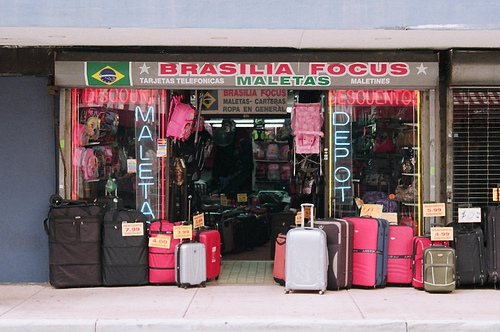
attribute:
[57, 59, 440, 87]
sign — green, yellow, white, grey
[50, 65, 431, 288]
storefront — gated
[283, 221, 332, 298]
luggage — silver, for sale, tall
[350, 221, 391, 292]
bag — luggage, pink, black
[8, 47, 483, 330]
store — brazillian, big, luggage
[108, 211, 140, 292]
luggage — black, large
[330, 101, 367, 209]
sign — neon, blue, depot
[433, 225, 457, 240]
tag — price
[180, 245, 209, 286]
bag — grey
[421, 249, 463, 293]
luggage — greenish, brown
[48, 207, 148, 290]
bags — black, luggage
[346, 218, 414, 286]
bags — pink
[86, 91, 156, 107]
sign — pink, discount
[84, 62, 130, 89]
flag — brazillian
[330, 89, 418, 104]
lettering — spanish, pink, desquentos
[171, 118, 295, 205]
inside — dark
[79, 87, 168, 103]
discount — written, red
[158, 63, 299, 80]
brasilia — red, written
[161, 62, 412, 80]
writing — red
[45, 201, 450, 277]
suitcases — black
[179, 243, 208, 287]
suitcase — white, grey, small, pink, silver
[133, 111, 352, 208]
signs — neon, green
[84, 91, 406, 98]
signs — neon, red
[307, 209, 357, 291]
suitcase — brown, large, pink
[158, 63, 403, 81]
lettering — green, red, white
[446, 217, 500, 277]
suitcase — black, large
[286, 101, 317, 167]
stroller — pink, hanging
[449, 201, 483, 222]
sign — white